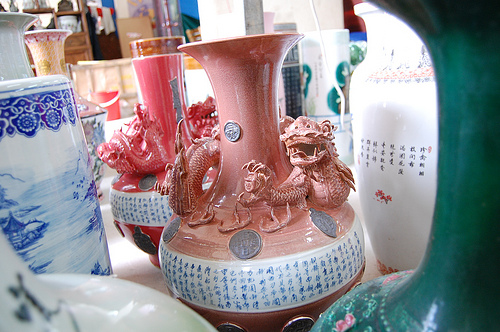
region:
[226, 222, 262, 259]
coin on a vase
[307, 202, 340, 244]
coin on a vase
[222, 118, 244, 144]
coin on a vase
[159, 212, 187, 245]
coin on a vase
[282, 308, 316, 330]
coin on a vase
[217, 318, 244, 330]
coin on a vase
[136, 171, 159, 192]
coin on a vase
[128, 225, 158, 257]
coin on a vase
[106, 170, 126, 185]
coin on a vase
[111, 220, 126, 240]
coin on a vase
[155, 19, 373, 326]
brown vase with a chinese dragon on it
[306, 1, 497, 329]
green vase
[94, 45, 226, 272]
red vase with chinese dragon on it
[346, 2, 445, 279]
white vase with chinese lettering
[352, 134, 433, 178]
chinese lettering is black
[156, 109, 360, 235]
ceramic dragon on vase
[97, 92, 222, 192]
red ceramic dragon on vase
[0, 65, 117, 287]
white vase with blue design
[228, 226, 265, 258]
silver coin embedded in vase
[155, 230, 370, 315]
blue chinese lettering on vase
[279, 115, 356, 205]
pink ceramic dragon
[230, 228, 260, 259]
silver round decor on vase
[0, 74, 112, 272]
blue and white decorative vase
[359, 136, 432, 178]
asian writing on the white vase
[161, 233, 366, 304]
blue asian writing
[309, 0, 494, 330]
tall green ceramic vase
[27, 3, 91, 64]
wooden cabinet in the background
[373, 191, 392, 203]
pink flower on the white vase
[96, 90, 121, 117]
small red bucket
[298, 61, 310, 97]
green flower on the white vase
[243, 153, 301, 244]
part of a statue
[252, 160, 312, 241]
part of a staue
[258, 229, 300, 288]
part of a vase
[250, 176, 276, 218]
part of a statue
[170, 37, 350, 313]
brown vase with dragon sculpture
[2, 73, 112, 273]
blue and white vase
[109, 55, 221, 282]
red vase with dragon sculpture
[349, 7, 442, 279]
white vase with black lettering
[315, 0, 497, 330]
dark green vase on the right side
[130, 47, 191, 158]
neck of red vase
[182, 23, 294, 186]
neck of brown vase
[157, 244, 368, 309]
white band on brown vase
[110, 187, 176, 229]
white band on red vase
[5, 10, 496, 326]
group of vase sitting on the table